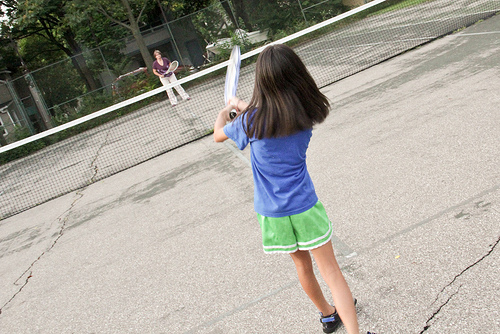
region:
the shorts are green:
[239, 194, 347, 254]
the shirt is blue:
[222, 108, 349, 227]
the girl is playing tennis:
[206, 44, 360, 332]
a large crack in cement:
[9, 190, 107, 321]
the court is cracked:
[41, 125, 120, 328]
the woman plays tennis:
[132, 48, 195, 110]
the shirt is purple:
[148, 48, 174, 80]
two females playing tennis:
[141, 38, 368, 332]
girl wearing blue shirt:
[210, 53, 351, 327]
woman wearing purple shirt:
[151, 49, 188, 107]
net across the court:
[0, 0, 485, 209]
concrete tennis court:
[6, 2, 498, 332]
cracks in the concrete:
[7, 119, 492, 332]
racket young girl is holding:
[216, 44, 250, 121]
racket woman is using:
[164, 59, 178, 73]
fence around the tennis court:
[0, 1, 361, 132]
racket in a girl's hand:
[221, 44, 244, 114]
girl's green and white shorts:
[251, 200, 335, 257]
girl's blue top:
[221, 102, 322, 217]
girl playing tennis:
[210, 38, 376, 332]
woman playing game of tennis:
[149, 47, 194, 107]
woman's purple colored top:
[146, 55, 173, 80]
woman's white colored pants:
[157, 71, 187, 102]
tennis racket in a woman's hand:
[164, 59, 181, 75]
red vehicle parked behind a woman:
[106, 60, 191, 100]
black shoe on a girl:
[309, 293, 359, 332]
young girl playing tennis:
[214, 35, 378, 332]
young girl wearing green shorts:
[208, 39, 375, 331]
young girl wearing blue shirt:
[212, 43, 379, 332]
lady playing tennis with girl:
[148, 47, 191, 109]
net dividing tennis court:
[2, 0, 497, 231]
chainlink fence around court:
[0, 0, 312, 132]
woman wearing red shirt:
[150, 46, 191, 108]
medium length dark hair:
[234, 45, 334, 141]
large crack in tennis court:
[1, 119, 113, 310]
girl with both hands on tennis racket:
[210, 39, 360, 331]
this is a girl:
[205, 35, 391, 332]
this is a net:
[0, 0, 497, 212]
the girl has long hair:
[239, 43, 341, 145]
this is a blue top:
[232, 103, 332, 221]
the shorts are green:
[248, 194, 338, 259]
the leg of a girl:
[299, 223, 383, 332]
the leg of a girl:
[277, 235, 362, 331]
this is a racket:
[212, 46, 257, 127]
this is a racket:
[163, 53, 190, 80]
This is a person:
[143, 38, 199, 113]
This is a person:
[212, 30, 385, 331]